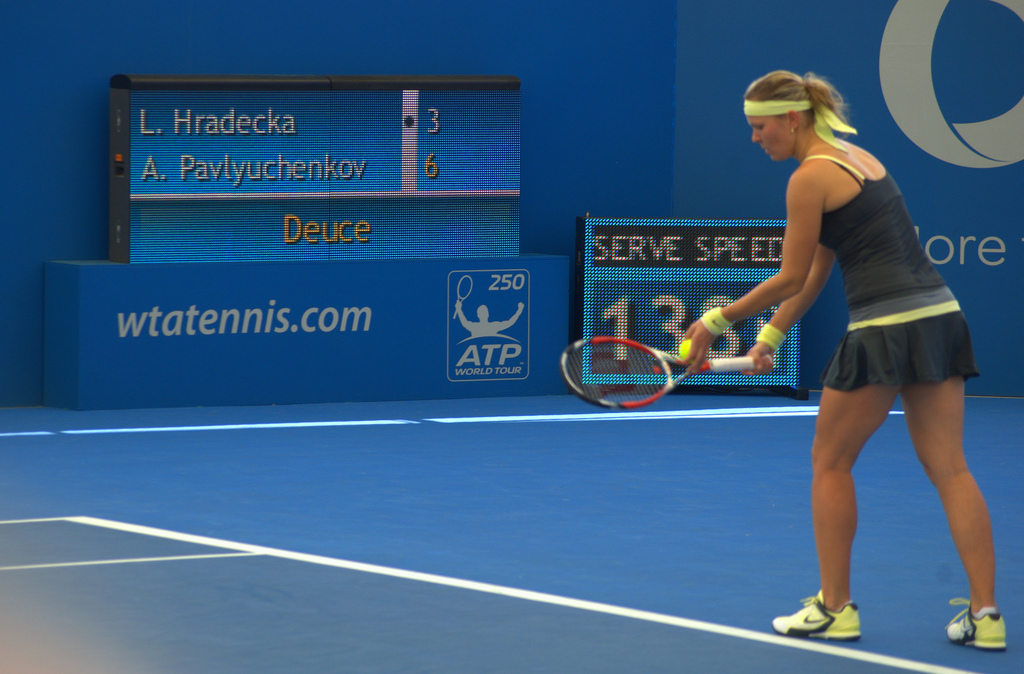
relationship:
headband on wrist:
[751, 312, 786, 354] [756, 340, 783, 360]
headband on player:
[740, 87, 818, 120] [679, 69, 1007, 651]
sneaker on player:
[762, 575, 875, 647] [679, 69, 1007, 651]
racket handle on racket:
[707, 354, 772, 372] [555, 329, 703, 420]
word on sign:
[592, 229, 787, 268] [575, 208, 805, 407]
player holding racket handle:
[679, 69, 1007, 651] [707, 354, 772, 372]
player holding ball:
[679, 69, 1007, 651] [667, 329, 704, 362]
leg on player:
[905, 376, 1001, 614] [679, 69, 1007, 651]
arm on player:
[672, 180, 826, 373] [679, 69, 1007, 651]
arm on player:
[673, 177, 837, 374] [679, 69, 1007, 651]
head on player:
[745, 55, 851, 166] [679, 69, 1007, 651]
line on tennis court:
[63, 510, 971, 670] [0, 410, 1022, 665]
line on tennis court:
[0, 543, 273, 576] [0, 410, 1022, 665]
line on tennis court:
[0, 508, 93, 526] [0, 410, 1022, 665]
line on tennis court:
[2, 396, 906, 440] [0, 410, 1022, 665]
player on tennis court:
[679, 69, 1007, 651] [0, 410, 1022, 665]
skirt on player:
[816, 292, 983, 396] [679, 69, 1007, 651]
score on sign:
[125, 91, 448, 195] [107, 75, 521, 264]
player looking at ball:
[679, 69, 1007, 651] [672, 324, 699, 363]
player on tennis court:
[679, 69, 1007, 651] [0, 381, 1022, 665]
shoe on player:
[938, 592, 1016, 655] [665, 63, 1013, 653]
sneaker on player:
[772, 590, 862, 642] [665, 63, 1013, 653]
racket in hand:
[559, 335, 773, 409] [734, 325, 787, 378]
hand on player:
[734, 325, 787, 378] [679, 69, 1007, 651]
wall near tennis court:
[0, 0, 1024, 400] [0, 381, 1022, 665]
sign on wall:
[97, 68, 536, 261] [0, 0, 1024, 400]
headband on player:
[744, 100, 813, 117] [679, 69, 1007, 651]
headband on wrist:
[756, 322, 786, 349] [748, 315, 787, 350]